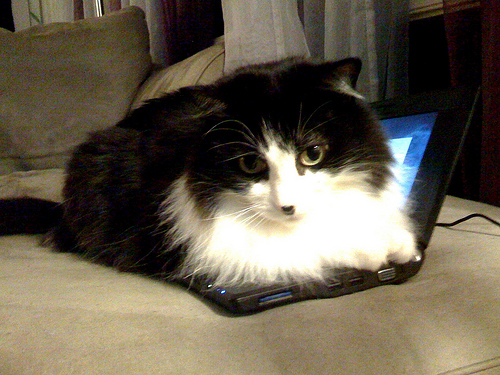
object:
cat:
[0, 55, 419, 287]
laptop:
[178, 85, 481, 316]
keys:
[177, 242, 366, 291]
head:
[180, 55, 383, 232]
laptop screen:
[370, 109, 441, 200]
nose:
[281, 203, 296, 214]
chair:
[1, 185, 499, 374]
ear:
[140, 82, 228, 119]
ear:
[318, 56, 363, 102]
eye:
[236, 152, 267, 174]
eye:
[297, 141, 328, 166]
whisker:
[215, 149, 262, 174]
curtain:
[221, 0, 414, 103]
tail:
[0, 197, 69, 236]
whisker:
[197, 201, 264, 225]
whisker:
[302, 114, 340, 148]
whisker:
[198, 117, 258, 144]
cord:
[435, 211, 499, 232]